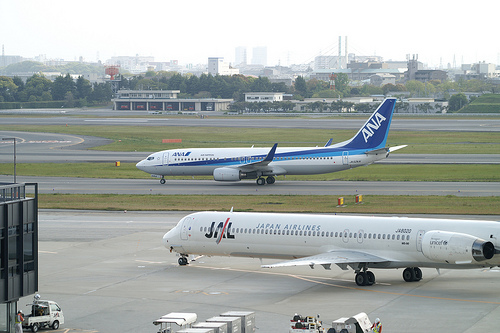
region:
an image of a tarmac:
[1, 106, 493, 331]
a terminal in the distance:
[89, 78, 498, 137]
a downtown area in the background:
[3, 34, 493, 95]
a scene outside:
[5, 12, 495, 322]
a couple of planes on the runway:
[132, 96, 498, 284]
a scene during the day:
[3, 3, 498, 326]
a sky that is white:
[1, 1, 493, 77]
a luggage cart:
[15, 284, 68, 331]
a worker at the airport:
[361, 312, 387, 331]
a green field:
[106, 119, 498, 159]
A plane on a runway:
[115, 98, 424, 215]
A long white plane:
[148, 183, 488, 330]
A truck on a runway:
[17, 290, 70, 332]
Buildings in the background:
[64, 0, 492, 122]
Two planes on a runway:
[1, 1, 498, 332]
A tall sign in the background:
[100, 59, 127, 100]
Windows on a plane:
[263, 226, 331, 244]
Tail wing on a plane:
[320, 78, 444, 227]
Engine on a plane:
[406, 216, 498, 291]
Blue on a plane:
[135, 91, 455, 211]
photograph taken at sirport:
[30, 57, 472, 314]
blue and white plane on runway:
[138, 92, 423, 200]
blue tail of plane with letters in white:
[347, 97, 402, 162]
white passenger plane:
[156, 201, 493, 283]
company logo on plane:
[195, 222, 248, 244]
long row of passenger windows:
[196, 220, 413, 240]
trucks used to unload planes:
[15, 291, 67, 330]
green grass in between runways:
[425, 110, 492, 217]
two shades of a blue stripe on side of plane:
[182, 143, 350, 166]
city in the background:
[27, 42, 431, 85]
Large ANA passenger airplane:
[129, 92, 404, 184]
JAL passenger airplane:
[157, 182, 499, 285]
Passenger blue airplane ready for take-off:
[134, 96, 405, 186]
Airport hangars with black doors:
[109, 87, 239, 112]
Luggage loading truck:
[16, 295, 64, 327]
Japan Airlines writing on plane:
[254, 220, 326, 230]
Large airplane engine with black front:
[422, 230, 497, 265]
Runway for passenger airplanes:
[1, 172, 498, 199]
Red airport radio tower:
[99, 62, 123, 86]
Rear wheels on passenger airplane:
[356, 265, 431, 289]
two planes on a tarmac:
[131, 96, 496, 286]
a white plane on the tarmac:
[160, 205, 495, 285]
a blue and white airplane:
[132, 95, 407, 182]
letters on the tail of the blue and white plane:
[360, 107, 385, 142]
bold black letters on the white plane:
[201, 220, 231, 240]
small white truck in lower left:
[21, 296, 61, 327]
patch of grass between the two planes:
[22, 191, 497, 211]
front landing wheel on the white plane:
[175, 252, 186, 262]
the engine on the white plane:
[420, 230, 495, 260]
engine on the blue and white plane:
[213, 165, 244, 181]